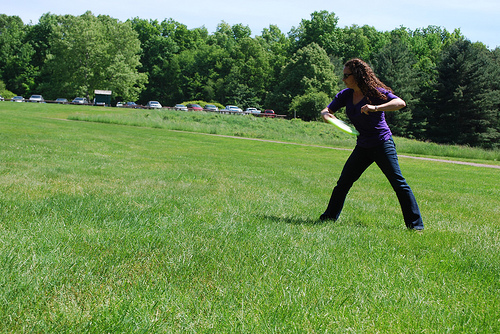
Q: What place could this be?
A: It is a field.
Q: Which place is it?
A: It is a field.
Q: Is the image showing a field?
A: Yes, it is showing a field.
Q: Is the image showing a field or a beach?
A: It is showing a field.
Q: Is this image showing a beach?
A: No, the picture is showing a field.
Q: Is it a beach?
A: No, it is a field.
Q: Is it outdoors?
A: Yes, it is outdoors.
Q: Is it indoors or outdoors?
A: It is outdoors.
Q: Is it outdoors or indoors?
A: It is outdoors.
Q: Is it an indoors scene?
A: No, it is outdoors.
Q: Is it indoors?
A: No, it is outdoors.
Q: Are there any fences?
A: No, there are no fences.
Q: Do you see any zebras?
A: Yes, there is a zebra.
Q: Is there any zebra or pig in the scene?
A: Yes, there is a zebra.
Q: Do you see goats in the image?
A: No, there are no goats.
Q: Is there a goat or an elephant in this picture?
A: No, there are no goats or elephants.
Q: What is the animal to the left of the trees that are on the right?
A: The animal is a zebra.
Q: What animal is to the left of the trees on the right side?
A: The animal is a zebra.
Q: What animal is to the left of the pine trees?
A: The animal is a zebra.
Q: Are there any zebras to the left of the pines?
A: Yes, there is a zebra to the left of the pines.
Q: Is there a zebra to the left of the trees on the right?
A: Yes, there is a zebra to the left of the pines.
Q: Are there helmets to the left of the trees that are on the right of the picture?
A: No, there is a zebra to the left of the pine trees.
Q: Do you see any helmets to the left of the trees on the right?
A: No, there is a zebra to the left of the pine trees.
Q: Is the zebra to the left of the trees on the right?
A: Yes, the zebra is to the left of the pines.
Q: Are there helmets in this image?
A: No, there are no helmets.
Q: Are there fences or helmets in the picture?
A: No, there are no helmets or fences.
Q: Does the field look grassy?
A: Yes, the field is grassy.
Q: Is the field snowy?
A: No, the field is grassy.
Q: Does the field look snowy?
A: No, the field is grassy.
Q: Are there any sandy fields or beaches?
A: No, there is a field but it is grassy.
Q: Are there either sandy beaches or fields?
A: No, there is a field but it is grassy.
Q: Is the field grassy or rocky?
A: The field is grassy.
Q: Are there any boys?
A: No, there are no boys.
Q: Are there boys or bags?
A: No, there are no boys or bags.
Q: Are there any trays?
A: No, there are no trays.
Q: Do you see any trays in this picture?
A: No, there are no trays.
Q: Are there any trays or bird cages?
A: No, there are no trays or bird cages.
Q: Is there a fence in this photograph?
A: No, there are no fences.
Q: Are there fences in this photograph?
A: No, there are no fences.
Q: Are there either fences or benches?
A: No, there are no fences or benches.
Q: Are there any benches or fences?
A: No, there are no fences or benches.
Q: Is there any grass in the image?
A: Yes, there is grass.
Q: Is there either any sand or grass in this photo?
A: Yes, there is grass.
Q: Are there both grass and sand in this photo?
A: No, there is grass but no sand.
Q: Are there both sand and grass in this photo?
A: No, there is grass but no sand.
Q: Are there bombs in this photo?
A: No, there are no bombs.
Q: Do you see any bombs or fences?
A: No, there are no bombs or fences.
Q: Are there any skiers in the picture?
A: No, there are no skiers.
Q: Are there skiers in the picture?
A: No, there are no skiers.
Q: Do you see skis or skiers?
A: No, there are no skiers or skis.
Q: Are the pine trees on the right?
A: Yes, the pine trees are on the right of the image.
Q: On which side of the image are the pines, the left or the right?
A: The pines are on the right of the image.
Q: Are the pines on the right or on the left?
A: The pines are on the right of the image.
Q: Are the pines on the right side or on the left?
A: The pines are on the right of the image.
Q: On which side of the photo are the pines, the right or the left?
A: The pines are on the right of the image.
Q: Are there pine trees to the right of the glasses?
A: Yes, there are pine trees to the right of the glasses.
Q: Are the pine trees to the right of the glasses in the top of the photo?
A: Yes, the pine trees are to the right of the glasses.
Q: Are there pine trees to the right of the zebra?
A: Yes, there are pine trees to the right of the zebra.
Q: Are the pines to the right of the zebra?
A: Yes, the pines are to the right of the zebra.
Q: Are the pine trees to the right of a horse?
A: No, the pine trees are to the right of the zebra.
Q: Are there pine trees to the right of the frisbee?
A: Yes, there are pine trees to the right of the frisbee.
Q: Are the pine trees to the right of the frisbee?
A: Yes, the pine trees are to the right of the frisbee.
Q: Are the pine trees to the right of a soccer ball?
A: No, the pine trees are to the right of the frisbee.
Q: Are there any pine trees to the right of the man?
A: Yes, there are pine trees to the right of the man.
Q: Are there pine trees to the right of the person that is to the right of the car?
A: Yes, there are pine trees to the right of the man.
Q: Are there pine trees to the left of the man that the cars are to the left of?
A: No, the pine trees are to the right of the man.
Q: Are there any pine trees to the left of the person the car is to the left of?
A: No, the pine trees are to the right of the man.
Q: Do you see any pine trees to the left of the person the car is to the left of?
A: No, the pine trees are to the right of the man.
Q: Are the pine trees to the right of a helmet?
A: No, the pine trees are to the right of the man.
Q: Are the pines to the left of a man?
A: No, the pines are to the right of a man.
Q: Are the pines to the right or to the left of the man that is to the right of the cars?
A: The pines are to the right of the man.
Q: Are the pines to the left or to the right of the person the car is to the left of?
A: The pines are to the right of the man.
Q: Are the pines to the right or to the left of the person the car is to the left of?
A: The pines are to the right of the man.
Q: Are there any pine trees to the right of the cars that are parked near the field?
A: Yes, there are pine trees to the right of the cars.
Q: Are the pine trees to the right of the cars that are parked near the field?
A: Yes, the pine trees are to the right of the cars.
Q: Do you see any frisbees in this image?
A: Yes, there is a frisbee.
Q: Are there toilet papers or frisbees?
A: Yes, there is a frisbee.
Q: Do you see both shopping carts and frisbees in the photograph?
A: No, there is a frisbee but no shopping carts.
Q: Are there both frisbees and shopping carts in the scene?
A: No, there is a frisbee but no shopping carts.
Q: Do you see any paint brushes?
A: No, there are no paint brushes.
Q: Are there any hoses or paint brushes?
A: No, there are no paint brushes or hoses.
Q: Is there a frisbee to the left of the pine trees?
A: Yes, there is a frisbee to the left of the pine trees.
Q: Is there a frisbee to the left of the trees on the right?
A: Yes, there is a frisbee to the left of the pine trees.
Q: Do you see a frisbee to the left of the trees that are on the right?
A: Yes, there is a frisbee to the left of the pine trees.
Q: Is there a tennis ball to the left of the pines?
A: No, there is a frisbee to the left of the pines.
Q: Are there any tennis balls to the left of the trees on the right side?
A: No, there is a frisbee to the left of the pines.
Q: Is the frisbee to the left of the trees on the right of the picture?
A: Yes, the frisbee is to the left of the pines.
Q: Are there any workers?
A: No, there are no workers.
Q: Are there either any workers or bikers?
A: No, there are no workers or bikers.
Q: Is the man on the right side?
A: Yes, the man is on the right of the image.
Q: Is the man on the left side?
A: No, the man is on the right of the image.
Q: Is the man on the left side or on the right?
A: The man is on the right of the image.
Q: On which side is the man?
A: The man is on the right of the image.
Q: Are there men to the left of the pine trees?
A: Yes, there is a man to the left of the pine trees.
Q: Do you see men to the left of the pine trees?
A: Yes, there is a man to the left of the pine trees.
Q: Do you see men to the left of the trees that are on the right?
A: Yes, there is a man to the left of the pine trees.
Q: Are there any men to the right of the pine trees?
A: No, the man is to the left of the pine trees.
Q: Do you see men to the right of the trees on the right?
A: No, the man is to the left of the pine trees.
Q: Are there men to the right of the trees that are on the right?
A: No, the man is to the left of the pine trees.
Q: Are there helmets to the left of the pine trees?
A: No, there is a man to the left of the pine trees.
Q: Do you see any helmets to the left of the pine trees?
A: No, there is a man to the left of the pine trees.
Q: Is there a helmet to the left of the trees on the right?
A: No, there is a man to the left of the pine trees.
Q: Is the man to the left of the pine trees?
A: Yes, the man is to the left of the pine trees.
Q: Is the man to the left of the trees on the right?
A: Yes, the man is to the left of the pine trees.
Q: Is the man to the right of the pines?
A: No, the man is to the left of the pines.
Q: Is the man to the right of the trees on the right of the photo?
A: No, the man is to the left of the pines.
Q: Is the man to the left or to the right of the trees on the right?
A: The man is to the left of the pine trees.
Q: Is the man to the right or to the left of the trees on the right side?
A: The man is to the left of the pine trees.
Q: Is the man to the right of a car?
A: Yes, the man is to the right of a car.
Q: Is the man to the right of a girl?
A: No, the man is to the right of a car.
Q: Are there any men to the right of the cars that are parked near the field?
A: Yes, there is a man to the right of the cars.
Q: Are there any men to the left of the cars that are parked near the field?
A: No, the man is to the right of the cars.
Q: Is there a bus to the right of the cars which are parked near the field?
A: No, there is a man to the right of the cars.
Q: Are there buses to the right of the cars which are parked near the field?
A: No, there is a man to the right of the cars.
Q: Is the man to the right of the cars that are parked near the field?
A: Yes, the man is to the right of the cars.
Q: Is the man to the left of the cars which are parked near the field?
A: No, the man is to the right of the cars.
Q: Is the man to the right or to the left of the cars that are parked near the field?
A: The man is to the right of the cars.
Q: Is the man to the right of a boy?
A: No, the man is to the right of a car.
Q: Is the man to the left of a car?
A: No, the man is to the right of a car.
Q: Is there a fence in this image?
A: No, there are no fences.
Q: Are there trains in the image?
A: No, there are no trains.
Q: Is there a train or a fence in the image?
A: No, there are no trains or fences.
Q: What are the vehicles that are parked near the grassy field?
A: The vehicles are cars.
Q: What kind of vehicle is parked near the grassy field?
A: The vehicles are cars.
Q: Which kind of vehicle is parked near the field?
A: The vehicles are cars.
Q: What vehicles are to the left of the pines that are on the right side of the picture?
A: The vehicles are cars.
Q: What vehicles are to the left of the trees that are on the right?
A: The vehicles are cars.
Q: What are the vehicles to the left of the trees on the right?
A: The vehicles are cars.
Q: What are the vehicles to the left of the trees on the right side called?
A: The vehicles are cars.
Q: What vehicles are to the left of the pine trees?
A: The vehicles are cars.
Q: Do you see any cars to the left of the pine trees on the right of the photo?
A: Yes, there are cars to the left of the pine trees.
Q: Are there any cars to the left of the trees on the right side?
A: Yes, there are cars to the left of the pine trees.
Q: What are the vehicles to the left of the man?
A: The vehicles are cars.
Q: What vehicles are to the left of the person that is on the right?
A: The vehicles are cars.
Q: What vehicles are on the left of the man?
A: The vehicles are cars.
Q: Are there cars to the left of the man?
A: Yes, there are cars to the left of the man.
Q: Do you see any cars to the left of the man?
A: Yes, there are cars to the left of the man.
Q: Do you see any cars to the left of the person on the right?
A: Yes, there are cars to the left of the man.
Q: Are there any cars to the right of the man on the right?
A: No, the cars are to the left of the man.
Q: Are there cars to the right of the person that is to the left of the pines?
A: No, the cars are to the left of the man.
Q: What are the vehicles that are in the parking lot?
A: The vehicles are cars.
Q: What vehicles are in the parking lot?
A: The vehicles are cars.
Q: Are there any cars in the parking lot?
A: Yes, there are cars in the parking lot.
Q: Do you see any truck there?
A: No, there are no trucks.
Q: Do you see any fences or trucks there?
A: No, there are no trucks or fences.